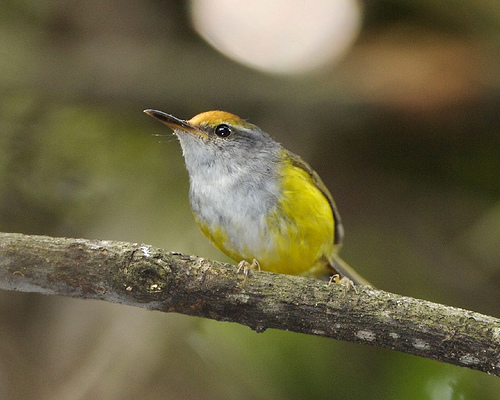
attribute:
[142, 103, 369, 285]
yellow bird — yellow , colorful, loverly, very beautiful, beautiful, white, gray, feathered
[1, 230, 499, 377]
tree branch — gray, little, spotted, white, long, thin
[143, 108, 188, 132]
sharp beak — black, tan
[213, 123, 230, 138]
round bird eye — small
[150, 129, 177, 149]
little whiskers — tiny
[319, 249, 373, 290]
feathers — gray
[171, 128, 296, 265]
feathers — white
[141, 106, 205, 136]
beak — small, long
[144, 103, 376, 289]
bird — white, gray, feathered, small, yellow, looking left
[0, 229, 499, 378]
branch — wood, light green, gray, tan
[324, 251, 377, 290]
tail — black, yellow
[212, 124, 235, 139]
eye — small, bright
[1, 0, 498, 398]
background — blurred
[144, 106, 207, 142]
beak — black, yellow, long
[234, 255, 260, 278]
foot — small, delicate